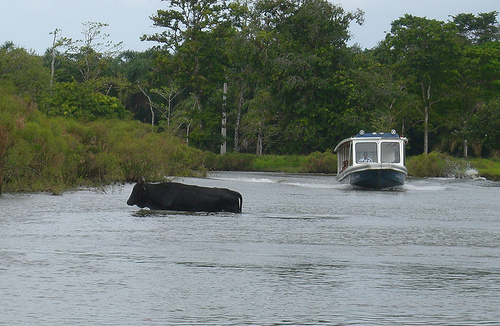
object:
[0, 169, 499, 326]
water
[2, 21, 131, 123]
trees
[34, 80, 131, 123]
leaves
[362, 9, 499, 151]
leaves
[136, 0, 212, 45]
leaves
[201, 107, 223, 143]
leaves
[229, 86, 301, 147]
leaves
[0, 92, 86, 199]
tree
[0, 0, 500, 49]
blue sky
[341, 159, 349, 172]
people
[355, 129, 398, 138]
blue top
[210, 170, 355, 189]
waves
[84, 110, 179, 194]
tree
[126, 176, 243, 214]
cow walking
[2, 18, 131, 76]
leaves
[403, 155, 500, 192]
wave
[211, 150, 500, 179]
shore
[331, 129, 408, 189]
boat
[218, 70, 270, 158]
trunk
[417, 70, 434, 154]
trunk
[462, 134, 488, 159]
trunk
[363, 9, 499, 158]
tree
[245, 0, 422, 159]
tree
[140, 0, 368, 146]
tree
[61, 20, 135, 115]
tree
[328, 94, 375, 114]
ground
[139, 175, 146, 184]
horns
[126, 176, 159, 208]
head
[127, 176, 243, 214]
cow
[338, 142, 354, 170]
mirrors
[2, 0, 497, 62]
sky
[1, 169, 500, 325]
creek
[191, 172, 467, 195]
path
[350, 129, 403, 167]
frame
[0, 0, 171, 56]
clouds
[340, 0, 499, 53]
clouds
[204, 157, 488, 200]
wake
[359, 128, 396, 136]
lights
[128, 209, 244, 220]
reflection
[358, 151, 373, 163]
man